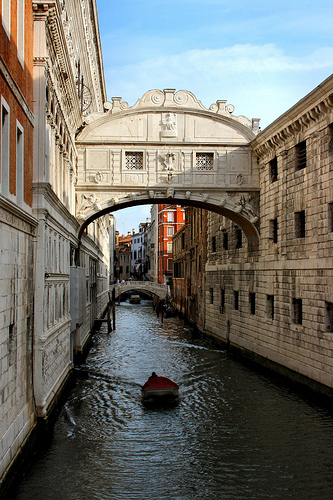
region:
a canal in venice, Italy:
[22, 13, 306, 420]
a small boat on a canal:
[138, 355, 176, 412]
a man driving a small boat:
[146, 366, 158, 384]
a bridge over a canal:
[105, 274, 175, 318]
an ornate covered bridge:
[69, 92, 269, 234]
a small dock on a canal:
[95, 305, 132, 343]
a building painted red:
[156, 211, 181, 295]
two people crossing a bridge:
[117, 274, 127, 286]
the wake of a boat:
[91, 362, 128, 402]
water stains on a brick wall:
[270, 268, 301, 315]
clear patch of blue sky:
[101, 9, 180, 27]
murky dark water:
[112, 450, 198, 496]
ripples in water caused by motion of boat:
[93, 376, 128, 441]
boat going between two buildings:
[140, 370, 179, 405]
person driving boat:
[150, 370, 156, 379]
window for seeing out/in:
[262, 294, 275, 321]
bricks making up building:
[233, 321, 276, 342]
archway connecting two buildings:
[82, 91, 261, 249]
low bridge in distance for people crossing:
[111, 278, 169, 302]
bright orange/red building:
[158, 211, 181, 228]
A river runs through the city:
[2, 2, 329, 498]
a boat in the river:
[134, 366, 184, 407]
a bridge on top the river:
[77, 69, 272, 410]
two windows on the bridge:
[117, 140, 219, 178]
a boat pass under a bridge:
[109, 275, 170, 309]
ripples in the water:
[72, 419, 285, 498]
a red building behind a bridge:
[117, 199, 190, 305]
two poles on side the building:
[87, 282, 125, 339]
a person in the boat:
[131, 357, 182, 411]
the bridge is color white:
[78, 83, 259, 237]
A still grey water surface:
[190, 436, 325, 491]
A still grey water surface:
[39, 432, 154, 496]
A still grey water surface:
[191, 353, 274, 432]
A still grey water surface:
[80, 365, 149, 423]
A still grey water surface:
[96, 327, 188, 356]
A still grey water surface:
[118, 301, 154, 332]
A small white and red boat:
[135, 364, 180, 405]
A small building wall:
[287, 292, 307, 328]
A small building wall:
[243, 287, 262, 315]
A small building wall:
[288, 209, 307, 236]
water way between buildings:
[101, 300, 246, 472]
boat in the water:
[130, 366, 190, 414]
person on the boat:
[143, 369, 156, 380]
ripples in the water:
[141, 436, 192, 461]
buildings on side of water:
[126, 170, 327, 358]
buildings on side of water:
[12, 139, 109, 412]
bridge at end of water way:
[108, 277, 171, 296]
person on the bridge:
[113, 275, 125, 287]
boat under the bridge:
[124, 292, 144, 304]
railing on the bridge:
[129, 279, 148, 284]